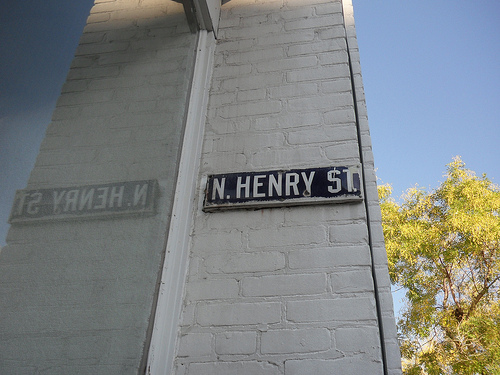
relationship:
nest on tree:
[451, 305, 465, 324] [423, 234, 488, 349]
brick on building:
[242, 73, 342, 130] [70, 4, 367, 362]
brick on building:
[258, 26, 318, 48] [139, 0, 400, 373]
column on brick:
[168, 1, 402, 372] [288, 244, 370, 270]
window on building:
[2, 2, 197, 373] [0, 0, 402, 373]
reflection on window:
[15, 80, 162, 330] [23, 29, 181, 336]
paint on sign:
[203, 196, 363, 212] [200, 162, 363, 212]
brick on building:
[230, 279, 307, 354] [0, 0, 402, 373]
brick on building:
[223, 1, 380, 360] [0, 0, 402, 373]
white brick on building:
[258, 327, 335, 354] [0, 0, 402, 373]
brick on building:
[241, 272, 329, 298] [139, 0, 400, 373]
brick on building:
[241, 270, 331, 300] [0, 0, 402, 373]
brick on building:
[196, 301, 282, 326] [0, 0, 402, 373]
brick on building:
[201, 248, 290, 275] [168, 1, 401, 373]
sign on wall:
[201, 171, 359, 211] [225, 0, 392, 345]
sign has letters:
[202, 162, 363, 218] [265, 171, 283, 198]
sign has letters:
[202, 162, 363, 218] [296, 172, 317, 197]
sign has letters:
[202, 162, 363, 218] [211, 177, 228, 199]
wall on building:
[232, 42, 347, 148] [0, 0, 402, 373]